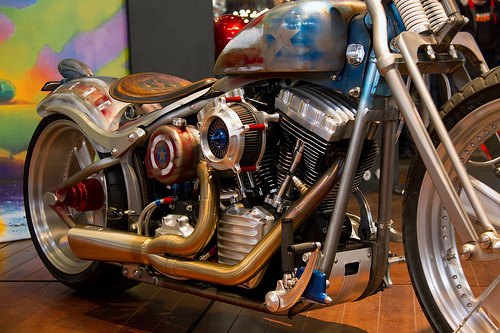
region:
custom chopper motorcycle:
[7, 2, 495, 332]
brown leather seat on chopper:
[118, 53, 243, 132]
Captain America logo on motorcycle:
[122, 113, 197, 185]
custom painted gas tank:
[199, 10, 338, 81]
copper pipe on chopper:
[29, 145, 376, 300]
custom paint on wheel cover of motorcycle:
[29, 53, 142, 145]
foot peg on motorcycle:
[244, 228, 320, 328]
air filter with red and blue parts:
[198, 90, 265, 182]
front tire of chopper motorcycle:
[388, 58, 487, 328]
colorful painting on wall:
[1, 6, 126, 234]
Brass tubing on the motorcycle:
[67, 228, 244, 288]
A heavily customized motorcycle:
[28, 14, 470, 320]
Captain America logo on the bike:
[142, 137, 186, 182]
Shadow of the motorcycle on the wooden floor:
[82, 280, 319, 330]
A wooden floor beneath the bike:
[280, 303, 434, 325]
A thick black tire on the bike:
[18, 126, 125, 288]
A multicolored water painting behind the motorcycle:
[0, 0, 127, 235]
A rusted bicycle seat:
[111, 68, 221, 97]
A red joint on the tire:
[56, 179, 104, 214]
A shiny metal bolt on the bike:
[344, 40, 372, 70]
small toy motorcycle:
[52, 45, 496, 250]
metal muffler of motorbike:
[58, 205, 192, 264]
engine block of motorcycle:
[249, 55, 365, 182]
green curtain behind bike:
[17, 15, 97, 155]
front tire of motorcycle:
[391, 119, 497, 245]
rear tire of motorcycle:
[29, 130, 133, 287]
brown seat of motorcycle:
[119, 59, 254, 126]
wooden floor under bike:
[334, 230, 467, 315]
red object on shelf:
[217, 10, 277, 52]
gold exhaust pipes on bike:
[161, 221, 301, 296]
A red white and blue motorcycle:
[18, 0, 499, 332]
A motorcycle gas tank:
[213, 1, 366, 77]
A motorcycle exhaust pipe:
[65, 225, 146, 270]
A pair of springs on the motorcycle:
[393, 0, 448, 32]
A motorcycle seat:
[106, 72, 218, 104]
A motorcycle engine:
[197, 84, 390, 287]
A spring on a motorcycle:
[388, 0, 430, 32]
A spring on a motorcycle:
[421, 0, 451, 28]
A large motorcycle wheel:
[18, 109, 138, 288]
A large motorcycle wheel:
[401, 65, 498, 331]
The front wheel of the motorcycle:
[404, 64, 499, 331]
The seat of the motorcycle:
[113, 70, 206, 101]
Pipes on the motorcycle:
[70, 170, 210, 258]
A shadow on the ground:
[112, 300, 367, 332]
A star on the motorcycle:
[269, 19, 296, 52]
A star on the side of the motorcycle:
[153, 143, 170, 165]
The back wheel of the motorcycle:
[28, 120, 127, 286]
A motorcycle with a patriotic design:
[32, 3, 494, 328]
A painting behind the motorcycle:
[0, 3, 123, 243]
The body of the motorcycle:
[73, 70, 364, 288]